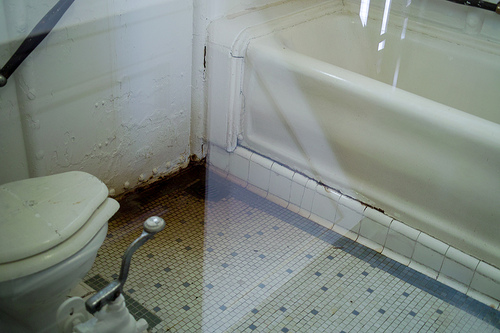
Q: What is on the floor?
A: Tile.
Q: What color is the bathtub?
A: White.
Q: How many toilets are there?
A: One.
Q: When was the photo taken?
A: Daytime.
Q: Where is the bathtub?
A: In the corner.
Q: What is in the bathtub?
A: Nothing.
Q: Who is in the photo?
A: Nobody.